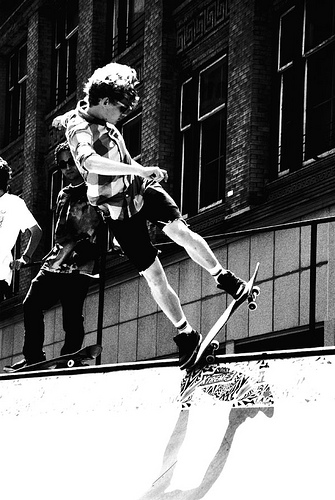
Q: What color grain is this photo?
A: Black and white.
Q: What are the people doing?
A: Skateboarding.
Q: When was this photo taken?
A: Daytime.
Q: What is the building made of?
A: Brick.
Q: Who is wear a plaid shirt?
A: Guy on skateboard.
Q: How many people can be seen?
A: 3.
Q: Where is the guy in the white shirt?
A: On the left.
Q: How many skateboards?
A: 2.